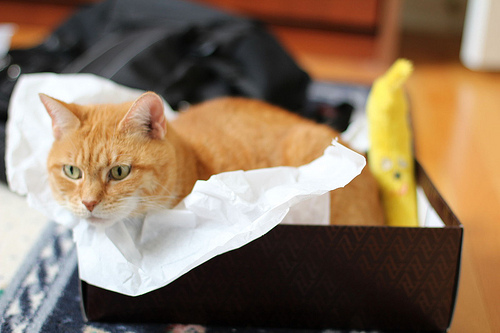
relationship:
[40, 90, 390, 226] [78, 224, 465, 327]
cat in box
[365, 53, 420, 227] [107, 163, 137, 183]
banana with eyes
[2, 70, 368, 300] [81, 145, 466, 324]
paper in box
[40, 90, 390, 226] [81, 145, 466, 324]
cat in box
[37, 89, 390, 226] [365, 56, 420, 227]
cat next to banana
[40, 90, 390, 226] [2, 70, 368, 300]
cat on paper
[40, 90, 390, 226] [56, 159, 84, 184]
cat has eye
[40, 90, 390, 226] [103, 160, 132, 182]
cat has eye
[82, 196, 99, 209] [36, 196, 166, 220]
nose between whiskers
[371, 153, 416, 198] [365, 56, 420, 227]
face on banana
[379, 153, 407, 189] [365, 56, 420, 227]
label on banana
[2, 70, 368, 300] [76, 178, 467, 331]
paper in box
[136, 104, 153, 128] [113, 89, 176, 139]
whiskers are in ear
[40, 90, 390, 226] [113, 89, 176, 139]
cat has ear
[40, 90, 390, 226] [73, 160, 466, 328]
cat in box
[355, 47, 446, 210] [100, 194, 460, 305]
banana in box